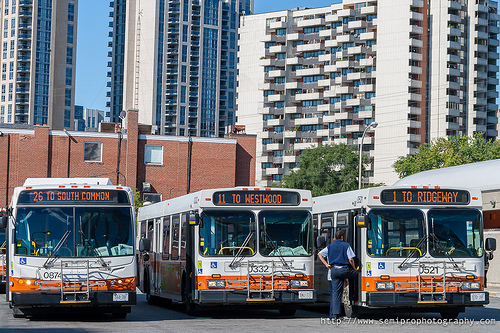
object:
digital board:
[213, 192, 298, 205]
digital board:
[385, 190, 467, 204]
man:
[316, 229, 359, 323]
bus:
[311, 184, 489, 320]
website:
[317, 316, 499, 328]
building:
[0, 109, 259, 210]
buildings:
[0, 0, 81, 133]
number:
[247, 263, 272, 275]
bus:
[136, 186, 316, 318]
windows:
[82, 141, 105, 165]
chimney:
[125, 108, 140, 201]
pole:
[358, 122, 372, 190]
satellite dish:
[117, 110, 127, 121]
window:
[16, 205, 137, 256]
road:
[0, 281, 499, 332]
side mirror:
[483, 237, 498, 253]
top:
[20, 176, 116, 187]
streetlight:
[370, 121, 379, 129]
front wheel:
[181, 273, 195, 316]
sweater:
[327, 239, 352, 268]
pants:
[330, 265, 359, 315]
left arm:
[317, 246, 332, 270]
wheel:
[440, 248, 470, 256]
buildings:
[230, 0, 499, 188]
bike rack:
[59, 259, 93, 303]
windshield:
[14, 206, 134, 258]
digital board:
[26, 189, 116, 201]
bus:
[4, 177, 139, 321]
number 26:
[32, 191, 44, 203]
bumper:
[7, 288, 137, 305]